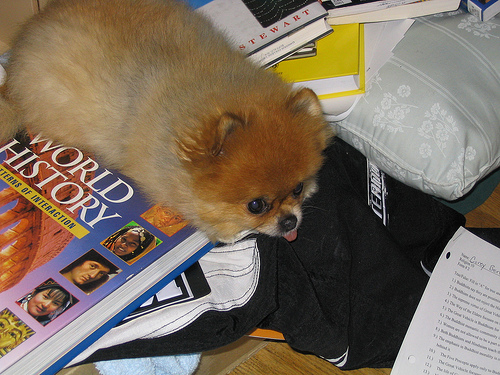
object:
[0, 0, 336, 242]
dog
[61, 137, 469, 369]
clothes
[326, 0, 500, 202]
pillow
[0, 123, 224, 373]
book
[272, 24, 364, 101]
book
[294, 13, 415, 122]
bunch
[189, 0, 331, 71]
books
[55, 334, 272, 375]
floor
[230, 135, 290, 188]
orange fur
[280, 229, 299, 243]
tongue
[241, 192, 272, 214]
eye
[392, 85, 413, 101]
flowers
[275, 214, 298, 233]
nose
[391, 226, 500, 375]
paper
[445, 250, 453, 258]
hole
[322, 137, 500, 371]
shorts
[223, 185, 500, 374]
desk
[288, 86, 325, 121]
ear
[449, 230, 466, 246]
staple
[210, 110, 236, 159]
ears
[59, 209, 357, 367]
sweatshirt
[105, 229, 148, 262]
head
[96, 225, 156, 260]
woman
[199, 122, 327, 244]
face